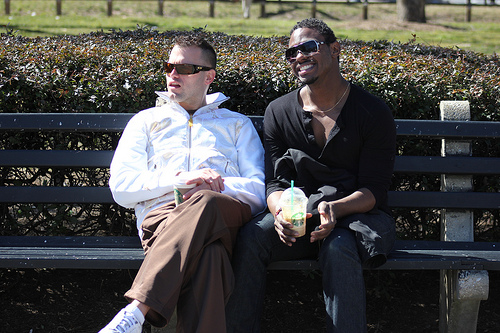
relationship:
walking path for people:
[0, 1, 498, 21] [98, 18, 395, 332]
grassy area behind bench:
[0, 1, 499, 55] [0, 101, 498, 332]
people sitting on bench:
[235, 18, 394, 332] [0, 101, 498, 332]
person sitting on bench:
[99, 37, 266, 333] [0, 101, 498, 332]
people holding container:
[235, 18, 394, 332] [279, 179, 308, 237]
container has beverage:
[279, 179, 308, 237] [283, 214, 307, 238]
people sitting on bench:
[98, 18, 395, 332] [0, 101, 498, 332]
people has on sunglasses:
[235, 18, 394, 332] [285, 39, 331, 61]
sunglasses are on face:
[285, 39, 331, 61] [286, 27, 330, 84]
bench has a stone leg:
[0, 101, 498, 332] [439, 268, 489, 333]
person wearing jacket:
[99, 37, 266, 333] [110, 92, 266, 230]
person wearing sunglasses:
[99, 37, 266, 333] [162, 61, 213, 75]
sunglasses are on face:
[162, 61, 213, 75] [166, 46, 205, 103]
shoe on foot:
[97, 310, 141, 333] [97, 307, 144, 333]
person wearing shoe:
[99, 37, 266, 333] [97, 310, 141, 333]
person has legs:
[99, 37, 266, 333] [96, 190, 251, 332]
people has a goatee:
[235, 18, 394, 332] [300, 77, 316, 84]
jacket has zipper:
[110, 92, 266, 230] [187, 111, 194, 179]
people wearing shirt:
[235, 18, 394, 332] [263, 84, 396, 216]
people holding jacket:
[235, 18, 394, 332] [110, 92, 266, 230]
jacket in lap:
[274, 148, 396, 267] [236, 201, 363, 265]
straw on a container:
[289, 178, 294, 213] [279, 179, 308, 237]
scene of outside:
[1, 1, 499, 332] [1, 1, 499, 332]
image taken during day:
[1, 1, 499, 332] [1, 2, 499, 333]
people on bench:
[235, 18, 394, 332] [0, 101, 498, 332]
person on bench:
[99, 37, 266, 333] [0, 101, 498, 332]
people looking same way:
[98, 18, 395, 332] [163, 19, 342, 102]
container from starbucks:
[279, 179, 308, 237] [290, 211, 305, 227]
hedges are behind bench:
[1, 24, 499, 241] [0, 101, 498, 332]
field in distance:
[0, 1, 499, 55] [1, 1, 498, 20]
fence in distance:
[1, 1, 499, 22] [1, 1, 498, 20]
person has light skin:
[99, 37, 266, 333] [164, 38, 224, 201]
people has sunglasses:
[235, 18, 394, 332] [285, 39, 331, 61]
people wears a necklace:
[235, 18, 394, 332] [300, 82, 350, 114]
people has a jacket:
[235, 18, 394, 332] [274, 148, 396, 267]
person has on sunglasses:
[99, 37, 266, 333] [162, 61, 213, 75]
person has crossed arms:
[99, 37, 266, 333] [109, 108, 266, 209]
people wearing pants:
[235, 18, 394, 332] [233, 208, 366, 332]